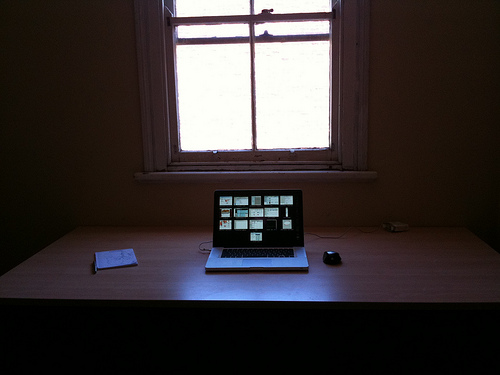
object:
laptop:
[204, 190, 309, 273]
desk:
[0, 228, 500, 372]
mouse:
[323, 250, 342, 266]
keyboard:
[221, 247, 295, 258]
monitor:
[218, 193, 299, 243]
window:
[174, 0, 333, 153]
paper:
[93, 247, 138, 273]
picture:
[250, 232, 263, 242]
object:
[383, 220, 408, 233]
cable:
[304, 223, 389, 239]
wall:
[0, 1, 500, 278]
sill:
[135, 0, 377, 181]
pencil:
[92, 250, 98, 273]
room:
[0, 0, 500, 374]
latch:
[258, 7, 275, 14]